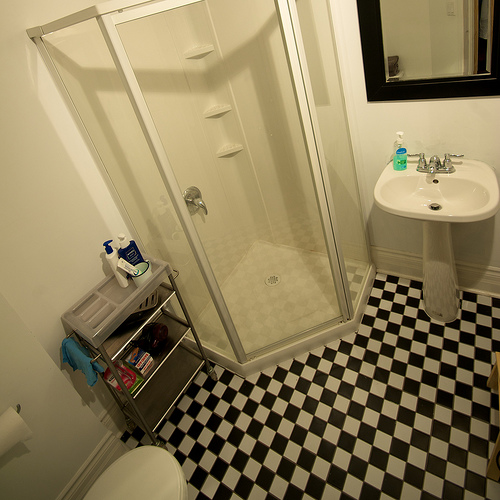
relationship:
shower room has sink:
[6, 5, 499, 499] [371, 153, 499, 218]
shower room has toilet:
[6, 5, 499, 499] [75, 441, 197, 497]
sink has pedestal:
[371, 150, 499, 223] [419, 214, 461, 320]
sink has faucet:
[371, 150, 499, 325] [405, 150, 465, 176]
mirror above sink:
[368, 2, 498, 94] [371, 150, 499, 325]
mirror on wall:
[368, 2, 498, 94] [349, 2, 498, 148]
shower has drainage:
[70, 37, 343, 362] [266, 269, 295, 294]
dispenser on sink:
[387, 127, 409, 177] [389, 151, 494, 223]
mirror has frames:
[354, 0, 500, 104] [355, 0, 496, 104]